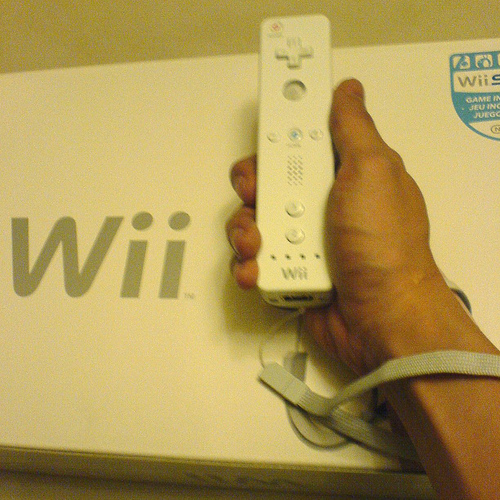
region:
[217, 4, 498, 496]
Hand holding a wii remote control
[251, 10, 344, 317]
Wii remote control is white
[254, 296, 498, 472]
Strap of wii control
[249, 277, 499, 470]
Strap around hand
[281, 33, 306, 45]
Command wii up button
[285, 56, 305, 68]
Command wii down button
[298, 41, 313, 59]
Command wii right button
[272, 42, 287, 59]
Command wii left button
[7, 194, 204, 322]
Word says Wii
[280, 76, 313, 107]
Left mouse button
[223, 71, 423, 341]
The person is holding a Wii game.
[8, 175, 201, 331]
The box has Wii written on it.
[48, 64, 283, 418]
The box is white.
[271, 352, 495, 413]
The string around the person wrist.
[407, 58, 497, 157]
The box has a blue emblem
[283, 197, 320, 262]
The game stick has two buttons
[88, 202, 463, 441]
The person hand is laying on the box.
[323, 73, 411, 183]
Thumb of a person hand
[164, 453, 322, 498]
Writing on the side of the box.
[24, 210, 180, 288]
The writing is gray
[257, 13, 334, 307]
white wii controller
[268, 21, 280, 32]
red power button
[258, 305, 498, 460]
gray wrist lanyard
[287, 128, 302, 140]
blue home button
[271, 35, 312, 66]
directional D pad button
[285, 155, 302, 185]
speaker holes on remote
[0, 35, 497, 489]
white cardboard box for wii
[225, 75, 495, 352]
right hand holding a wii remote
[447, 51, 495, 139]
blue wii sports symbol on box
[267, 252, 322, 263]
lights to indicate player number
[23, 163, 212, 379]
Box says Wii on it.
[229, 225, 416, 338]
Person holding wii remote.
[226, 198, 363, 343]
Wii remote is white in color.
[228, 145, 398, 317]
Remote is in person's right hand.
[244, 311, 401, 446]
Strap connected to wii remote.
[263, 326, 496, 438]
White strap around person's wrist.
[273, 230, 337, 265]
Round button on remote.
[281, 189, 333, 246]
Round button on remote.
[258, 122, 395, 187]
3 round buttons on remote.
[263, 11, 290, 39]
Power button to remote.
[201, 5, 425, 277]
remote in person's hand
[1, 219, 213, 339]
gray letters on surface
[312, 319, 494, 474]
gray wristband attached to remote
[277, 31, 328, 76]
directional pad on remote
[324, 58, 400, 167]
thumb of person's hand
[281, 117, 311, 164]
Button with the color blue on it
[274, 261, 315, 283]
The word "Wii" in gray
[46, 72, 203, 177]
white surface above word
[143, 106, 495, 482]
a person's arm and hand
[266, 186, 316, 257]
two buttons on lower part of remote